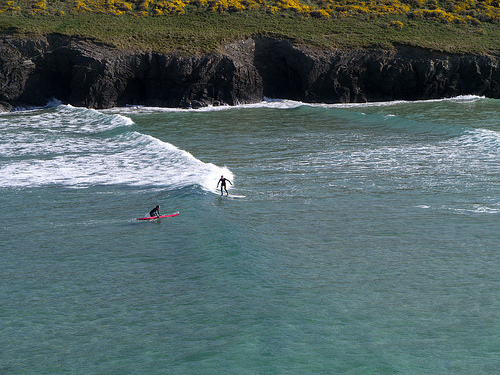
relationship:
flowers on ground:
[4, 0, 499, 27] [3, 0, 499, 50]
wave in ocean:
[44, 153, 100, 174] [0, 92, 499, 375]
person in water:
[146, 203, 166, 221] [1, 86, 499, 371]